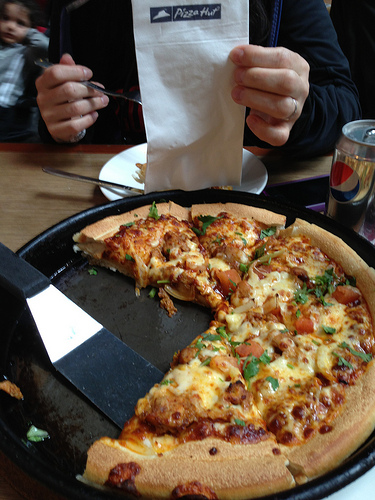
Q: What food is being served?
A: Pizza.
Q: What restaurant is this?
A: Pizza Hut.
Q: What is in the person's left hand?
A: A receipt.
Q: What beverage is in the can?
A: Pepsi.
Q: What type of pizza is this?
A: Deep dish pizza.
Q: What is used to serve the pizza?
A: A spatula.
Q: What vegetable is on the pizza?
A: Tomatoes.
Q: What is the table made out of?
A: Wood.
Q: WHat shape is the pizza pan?
A: Round.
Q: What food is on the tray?
A: Pizza.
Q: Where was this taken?
A: Pizza Hut.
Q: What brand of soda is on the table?
A: Pepsi.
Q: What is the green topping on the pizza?
A: Parsley.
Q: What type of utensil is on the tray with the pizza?
A: Spatula.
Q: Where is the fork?
A: In man's right hand.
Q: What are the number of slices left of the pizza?
A: 5.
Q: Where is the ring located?
A: Person's hand.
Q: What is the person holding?
A: White paper napkin.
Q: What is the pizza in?
A: A round black serving dish.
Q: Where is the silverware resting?
A: On a white plate.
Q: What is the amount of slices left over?
A: Six.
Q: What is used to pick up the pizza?
A: Spatula.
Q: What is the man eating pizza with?
A: A fork.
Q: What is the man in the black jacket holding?
A: A fork.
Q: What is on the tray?
A: Part of a pizza.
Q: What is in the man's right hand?
A: A napkin.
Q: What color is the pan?
A: Black.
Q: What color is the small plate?
A: White.